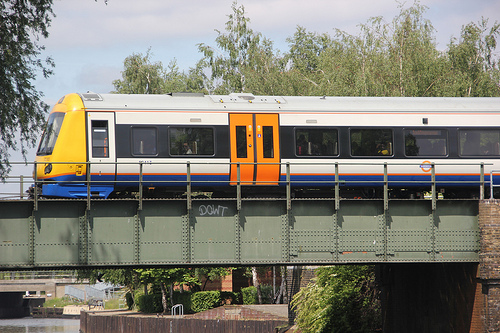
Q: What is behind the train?
A: Sky.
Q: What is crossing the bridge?
A: Train.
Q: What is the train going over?
A: The bridge.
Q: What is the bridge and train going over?
A: Water.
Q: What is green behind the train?
A: Trees.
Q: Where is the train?
A: On the bridge.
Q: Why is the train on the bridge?
A: To cross.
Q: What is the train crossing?
A: A road.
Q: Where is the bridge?
A: Over a road.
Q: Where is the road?
A: Under the bridge.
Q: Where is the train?
A: Over the road.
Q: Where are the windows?
A: On the train.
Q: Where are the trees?
A: Behind the train.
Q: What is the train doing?
A: Crossing a bridge.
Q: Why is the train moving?
A: To transport people.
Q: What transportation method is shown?
A: Train.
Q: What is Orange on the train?
A: Doors.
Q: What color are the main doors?
A: Orange.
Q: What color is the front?
A: Yellow.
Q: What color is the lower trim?
A: Blue.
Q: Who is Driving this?
A: Engineer.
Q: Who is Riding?
A: Passengers.